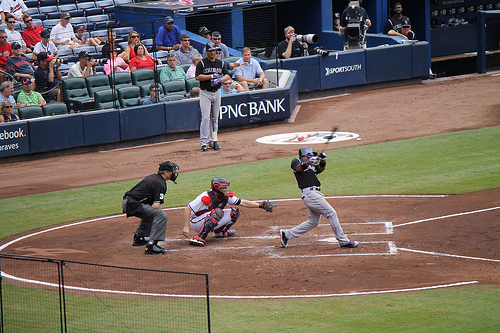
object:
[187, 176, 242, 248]
catcher uniform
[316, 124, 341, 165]
bat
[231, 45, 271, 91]
man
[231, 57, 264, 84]
shirt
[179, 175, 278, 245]
catcher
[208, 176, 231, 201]
head gear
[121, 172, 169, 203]
shirt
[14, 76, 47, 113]
man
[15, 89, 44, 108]
shirt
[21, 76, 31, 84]
hat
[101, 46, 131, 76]
woman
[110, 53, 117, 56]
sunglasses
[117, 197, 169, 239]
pants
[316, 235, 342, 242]
base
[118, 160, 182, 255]
umpire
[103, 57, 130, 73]
person top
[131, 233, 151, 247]
shoe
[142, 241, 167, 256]
shoe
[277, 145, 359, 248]
batter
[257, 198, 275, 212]
glove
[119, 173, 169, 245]
clothes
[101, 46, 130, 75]
person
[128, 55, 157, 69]
top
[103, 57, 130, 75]
shirt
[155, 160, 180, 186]
head gear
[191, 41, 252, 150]
player